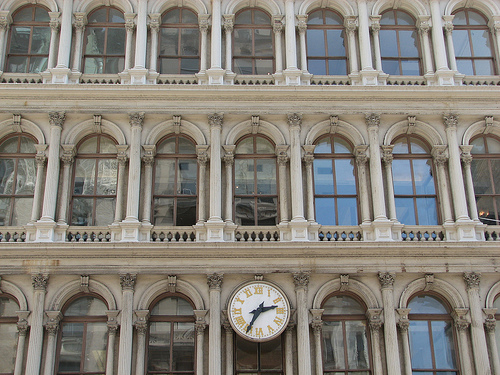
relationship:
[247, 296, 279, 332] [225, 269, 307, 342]
hands of clock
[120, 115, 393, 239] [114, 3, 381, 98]
posts holding up next floor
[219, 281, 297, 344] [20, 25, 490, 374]
clock attached to building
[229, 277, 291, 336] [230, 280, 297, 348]
numerals are attached to clock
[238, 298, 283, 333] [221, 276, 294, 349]
hands are attached to clock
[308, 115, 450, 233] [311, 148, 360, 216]
windows are reflecting sky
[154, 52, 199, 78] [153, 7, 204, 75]
boxes in windows